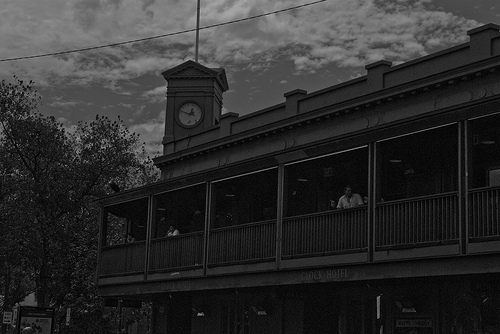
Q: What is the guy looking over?
A: A guy.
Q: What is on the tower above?
A: A clock.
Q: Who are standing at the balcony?
A: Men looking over.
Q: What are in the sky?
A: Clouds.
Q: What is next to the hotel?
A: The trees.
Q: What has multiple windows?
A: The balcony.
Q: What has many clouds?
A: The sky.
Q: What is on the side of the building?
A: The tree.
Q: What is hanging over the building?
A: The wire.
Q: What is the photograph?
A: Brown.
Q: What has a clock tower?
A: The wooden building.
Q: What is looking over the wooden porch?
A: The people.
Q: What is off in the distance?
A: The trees.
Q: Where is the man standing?
A: On the balcony.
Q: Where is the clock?
A: Front top of building.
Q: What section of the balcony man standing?
A: Fourth section from left.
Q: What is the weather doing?
A: Cloudy.